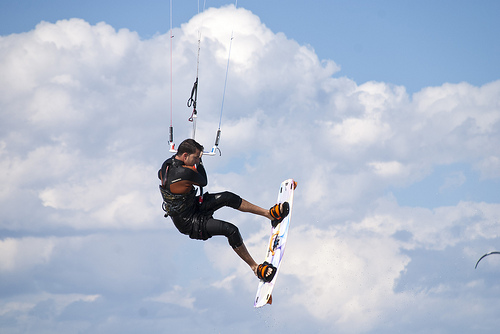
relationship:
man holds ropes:
[160, 143, 288, 278] [161, 3, 231, 155]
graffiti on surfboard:
[269, 225, 288, 266] [249, 178, 296, 306]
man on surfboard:
[160, 143, 288, 278] [249, 178, 296, 306]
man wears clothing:
[160, 143, 288, 278] [155, 165, 240, 245]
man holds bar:
[160, 143, 288, 278] [169, 138, 218, 156]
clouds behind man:
[1, 20, 496, 156] [160, 143, 288, 278]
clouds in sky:
[1, 20, 496, 156] [5, 1, 157, 331]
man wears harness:
[160, 143, 288, 278] [160, 156, 178, 187]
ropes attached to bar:
[161, 3, 231, 155] [169, 138, 218, 156]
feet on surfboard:
[257, 198, 286, 289] [249, 178, 296, 306]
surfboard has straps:
[249, 178, 296, 306] [255, 261, 267, 277]